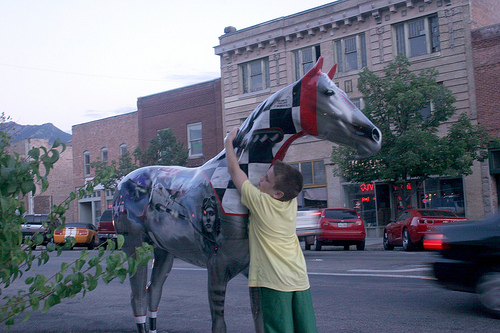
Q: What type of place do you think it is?
A: It is a street.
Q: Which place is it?
A: It is a street.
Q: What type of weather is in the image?
A: It is cloudy.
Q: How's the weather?
A: It is cloudy.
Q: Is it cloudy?
A: Yes, it is cloudy.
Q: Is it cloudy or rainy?
A: It is cloudy.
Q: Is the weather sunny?
A: No, it is cloudy.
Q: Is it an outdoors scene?
A: Yes, it is outdoors.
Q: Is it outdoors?
A: Yes, it is outdoors.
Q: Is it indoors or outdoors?
A: It is outdoors.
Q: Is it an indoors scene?
A: No, it is outdoors.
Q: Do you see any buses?
A: No, there are no buses.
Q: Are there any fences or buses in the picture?
A: No, there are no buses or fences.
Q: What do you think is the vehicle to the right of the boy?
A: The vehicle is a car.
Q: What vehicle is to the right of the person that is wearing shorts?
A: The vehicle is a car.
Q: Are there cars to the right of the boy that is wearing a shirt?
A: Yes, there is a car to the right of the boy.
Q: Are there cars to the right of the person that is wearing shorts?
A: Yes, there is a car to the right of the boy.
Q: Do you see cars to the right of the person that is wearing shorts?
A: Yes, there is a car to the right of the boy.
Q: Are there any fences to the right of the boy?
A: No, there is a car to the right of the boy.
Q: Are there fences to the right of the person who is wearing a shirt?
A: No, there is a car to the right of the boy.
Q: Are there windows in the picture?
A: Yes, there is a window.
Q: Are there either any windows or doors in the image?
A: Yes, there is a window.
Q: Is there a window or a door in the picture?
A: Yes, there is a window.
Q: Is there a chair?
A: No, there are no chairs.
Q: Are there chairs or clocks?
A: No, there are no chairs or clocks.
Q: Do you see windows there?
A: Yes, there is a window.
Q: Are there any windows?
A: Yes, there is a window.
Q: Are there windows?
A: Yes, there is a window.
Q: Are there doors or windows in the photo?
A: Yes, there is a window.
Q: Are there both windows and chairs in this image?
A: No, there is a window but no chairs.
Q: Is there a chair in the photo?
A: No, there are no chairs.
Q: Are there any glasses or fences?
A: No, there are no fences or glasses.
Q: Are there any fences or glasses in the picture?
A: No, there are no fences or glasses.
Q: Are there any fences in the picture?
A: No, there are no fences.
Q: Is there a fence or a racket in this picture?
A: No, there are no fences or rackets.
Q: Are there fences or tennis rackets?
A: No, there are no fences or tennis rackets.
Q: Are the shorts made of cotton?
A: Yes, the shorts are made of cotton.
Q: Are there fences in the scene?
A: No, there are no fences.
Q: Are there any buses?
A: No, there are no buses.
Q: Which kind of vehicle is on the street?
A: The vehicle is a car.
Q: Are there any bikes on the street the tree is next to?
A: No, there is a car on the street.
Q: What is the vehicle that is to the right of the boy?
A: The vehicle is a car.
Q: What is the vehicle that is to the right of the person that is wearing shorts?
A: The vehicle is a car.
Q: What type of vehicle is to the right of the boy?
A: The vehicle is a car.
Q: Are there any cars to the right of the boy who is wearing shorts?
A: Yes, there is a car to the right of the boy.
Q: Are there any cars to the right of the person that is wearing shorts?
A: Yes, there is a car to the right of the boy.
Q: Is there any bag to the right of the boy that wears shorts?
A: No, there is a car to the right of the boy.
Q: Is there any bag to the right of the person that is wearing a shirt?
A: No, there is a car to the right of the boy.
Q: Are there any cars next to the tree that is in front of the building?
A: Yes, there is a car next to the tree.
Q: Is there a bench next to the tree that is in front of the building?
A: No, there is a car next to the tree.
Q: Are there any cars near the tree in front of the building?
A: Yes, there is a car near the tree.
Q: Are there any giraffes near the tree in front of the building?
A: No, there is a car near the tree.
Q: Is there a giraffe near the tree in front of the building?
A: No, there is a car near the tree.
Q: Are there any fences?
A: No, there are no fences.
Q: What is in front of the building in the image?
A: The tree is in front of the building.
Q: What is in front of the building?
A: The tree is in front of the building.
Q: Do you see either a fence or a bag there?
A: No, there are no fences or bags.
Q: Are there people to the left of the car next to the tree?
A: Yes, there is a person to the left of the car.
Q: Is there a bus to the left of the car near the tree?
A: No, there is a person to the left of the car.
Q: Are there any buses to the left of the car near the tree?
A: No, there is a person to the left of the car.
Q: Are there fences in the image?
A: No, there are no fences.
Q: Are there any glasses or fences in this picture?
A: No, there are no fences or glasses.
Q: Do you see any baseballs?
A: No, there are no baseballs.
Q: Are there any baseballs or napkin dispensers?
A: No, there are no baseballs or napkin dispensers.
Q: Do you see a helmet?
A: No, there are no helmets.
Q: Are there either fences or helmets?
A: No, there are no helmets or fences.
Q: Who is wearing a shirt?
A: The boy is wearing a shirt.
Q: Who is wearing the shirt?
A: The boy is wearing a shirt.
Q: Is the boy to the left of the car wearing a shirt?
A: Yes, the boy is wearing a shirt.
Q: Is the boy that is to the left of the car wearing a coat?
A: No, the boy is wearing a shirt.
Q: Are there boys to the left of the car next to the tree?
A: Yes, there is a boy to the left of the car.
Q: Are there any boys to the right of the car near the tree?
A: No, the boy is to the left of the car.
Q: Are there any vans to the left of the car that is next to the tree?
A: No, there is a boy to the left of the car.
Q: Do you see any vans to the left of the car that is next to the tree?
A: No, there is a boy to the left of the car.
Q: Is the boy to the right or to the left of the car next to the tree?
A: The boy is to the left of the car.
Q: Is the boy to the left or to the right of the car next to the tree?
A: The boy is to the left of the car.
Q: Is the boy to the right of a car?
A: No, the boy is to the left of a car.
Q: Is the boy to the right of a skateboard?
A: No, the boy is to the right of the car.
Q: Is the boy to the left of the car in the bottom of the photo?
A: No, the boy is to the right of the car.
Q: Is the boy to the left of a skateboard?
A: No, the boy is to the left of the car.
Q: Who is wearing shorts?
A: The boy is wearing shorts.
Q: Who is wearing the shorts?
A: The boy is wearing shorts.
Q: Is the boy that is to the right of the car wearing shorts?
A: Yes, the boy is wearing shorts.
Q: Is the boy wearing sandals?
A: No, the boy is wearing shorts.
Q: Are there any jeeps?
A: No, there are no jeeps.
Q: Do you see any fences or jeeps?
A: No, there are no jeeps or fences.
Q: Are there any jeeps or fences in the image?
A: No, there are no jeeps or fences.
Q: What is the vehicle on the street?
A: The vehicle is a car.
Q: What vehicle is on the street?
A: The vehicle is a car.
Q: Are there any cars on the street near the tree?
A: Yes, there is a car on the street.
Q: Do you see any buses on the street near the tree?
A: No, there is a car on the street.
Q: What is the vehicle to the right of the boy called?
A: The vehicle is a car.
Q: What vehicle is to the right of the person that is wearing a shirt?
A: The vehicle is a car.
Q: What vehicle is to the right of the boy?
A: The vehicle is a car.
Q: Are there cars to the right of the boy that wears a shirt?
A: Yes, there is a car to the right of the boy.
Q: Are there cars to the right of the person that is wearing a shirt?
A: Yes, there is a car to the right of the boy.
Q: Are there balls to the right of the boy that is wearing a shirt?
A: No, there is a car to the right of the boy.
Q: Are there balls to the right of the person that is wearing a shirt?
A: No, there is a car to the right of the boy.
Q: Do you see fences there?
A: No, there are no fences.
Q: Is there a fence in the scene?
A: No, there are no fences.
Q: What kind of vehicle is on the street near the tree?
A: The vehicle is a car.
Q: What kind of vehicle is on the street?
A: The vehicle is a car.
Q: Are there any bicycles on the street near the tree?
A: No, there is a car on the street.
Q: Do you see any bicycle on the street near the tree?
A: No, there is a car on the street.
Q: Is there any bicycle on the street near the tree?
A: No, there is a car on the street.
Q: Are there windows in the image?
A: Yes, there is a window.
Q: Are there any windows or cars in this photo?
A: Yes, there is a window.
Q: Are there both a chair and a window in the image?
A: No, there is a window but no chairs.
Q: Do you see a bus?
A: No, there are no buses.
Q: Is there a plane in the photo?
A: No, there are no airplanes.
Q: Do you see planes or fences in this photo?
A: No, there are no planes or fences.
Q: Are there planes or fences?
A: No, there are no planes or fences.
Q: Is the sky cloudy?
A: Yes, the sky is cloudy.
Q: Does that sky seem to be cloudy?
A: Yes, the sky is cloudy.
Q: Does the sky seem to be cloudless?
A: No, the sky is cloudy.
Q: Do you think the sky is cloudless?
A: No, the sky is cloudy.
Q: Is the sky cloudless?
A: No, the sky is cloudy.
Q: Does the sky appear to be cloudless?
A: No, the sky is cloudy.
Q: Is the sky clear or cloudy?
A: The sky is cloudy.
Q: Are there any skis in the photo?
A: No, there are no skis.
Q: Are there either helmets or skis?
A: No, there are no skis or helmets.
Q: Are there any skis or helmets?
A: No, there are no skis or helmets.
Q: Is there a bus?
A: No, there are no buses.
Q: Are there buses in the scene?
A: No, there are no buses.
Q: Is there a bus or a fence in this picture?
A: No, there are no buses or fences.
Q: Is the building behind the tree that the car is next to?
A: Yes, the building is behind the tree.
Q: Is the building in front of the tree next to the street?
A: No, the building is behind the tree.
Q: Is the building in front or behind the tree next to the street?
A: The building is behind the tree.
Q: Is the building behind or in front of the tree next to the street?
A: The building is behind the tree.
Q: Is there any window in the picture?
A: Yes, there is a window.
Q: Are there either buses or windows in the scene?
A: Yes, there is a window.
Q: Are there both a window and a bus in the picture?
A: No, there is a window but no buses.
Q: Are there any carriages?
A: No, there are no carriages.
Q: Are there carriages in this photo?
A: No, there are no carriages.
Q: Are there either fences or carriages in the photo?
A: No, there are no carriages or fences.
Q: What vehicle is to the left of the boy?
A: The vehicle is a car.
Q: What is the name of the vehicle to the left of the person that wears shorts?
A: The vehicle is a car.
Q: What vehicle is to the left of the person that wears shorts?
A: The vehicle is a car.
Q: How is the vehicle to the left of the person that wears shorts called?
A: The vehicle is a car.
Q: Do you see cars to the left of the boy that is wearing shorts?
A: Yes, there is a car to the left of the boy.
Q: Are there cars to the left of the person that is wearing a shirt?
A: Yes, there is a car to the left of the boy.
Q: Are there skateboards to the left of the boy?
A: No, there is a car to the left of the boy.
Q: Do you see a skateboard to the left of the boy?
A: No, there is a car to the left of the boy.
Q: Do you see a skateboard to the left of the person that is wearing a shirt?
A: No, there is a car to the left of the boy.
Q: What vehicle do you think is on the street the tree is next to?
A: The vehicle is a car.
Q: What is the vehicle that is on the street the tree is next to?
A: The vehicle is a car.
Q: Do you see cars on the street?
A: Yes, there is a car on the street.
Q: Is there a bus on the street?
A: No, there is a car on the street.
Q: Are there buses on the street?
A: No, there is a car on the street.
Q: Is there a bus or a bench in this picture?
A: No, there are no buses or benches.